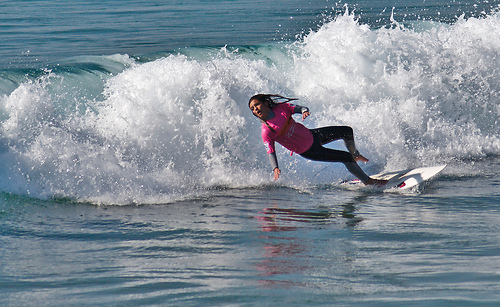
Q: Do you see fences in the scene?
A: No, there are no fences.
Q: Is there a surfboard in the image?
A: Yes, there is a surfboard.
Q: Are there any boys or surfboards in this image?
A: Yes, there is a surfboard.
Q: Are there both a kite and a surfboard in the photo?
A: No, there is a surfboard but no kites.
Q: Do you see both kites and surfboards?
A: No, there is a surfboard but no kites.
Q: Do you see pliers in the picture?
A: No, there are no pliers.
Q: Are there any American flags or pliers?
A: No, there are no pliers or American flags.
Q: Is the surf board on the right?
A: Yes, the surf board is on the right of the image.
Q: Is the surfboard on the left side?
A: No, the surfboard is on the right of the image.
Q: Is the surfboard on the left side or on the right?
A: The surfboard is on the right of the image.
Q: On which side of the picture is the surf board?
A: The surf board is on the right of the image.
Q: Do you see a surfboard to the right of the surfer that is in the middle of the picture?
A: Yes, there is a surfboard to the right of the surfer.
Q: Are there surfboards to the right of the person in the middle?
A: Yes, there is a surfboard to the right of the surfer.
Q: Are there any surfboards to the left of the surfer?
A: No, the surfboard is to the right of the surfer.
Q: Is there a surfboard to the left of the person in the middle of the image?
A: No, the surfboard is to the right of the surfer.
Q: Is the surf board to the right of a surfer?
A: Yes, the surf board is to the right of a surfer.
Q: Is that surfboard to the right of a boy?
A: No, the surfboard is to the right of a surfer.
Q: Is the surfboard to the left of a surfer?
A: No, the surfboard is to the right of a surfer.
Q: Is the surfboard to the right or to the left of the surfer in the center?
A: The surfboard is to the right of the surfer.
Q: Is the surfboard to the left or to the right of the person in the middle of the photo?
A: The surfboard is to the right of the surfer.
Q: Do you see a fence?
A: No, there are no fences.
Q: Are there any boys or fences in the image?
A: No, there are no fences or boys.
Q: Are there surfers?
A: Yes, there is a surfer.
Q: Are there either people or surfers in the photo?
A: Yes, there is a surfer.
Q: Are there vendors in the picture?
A: No, there are no vendors.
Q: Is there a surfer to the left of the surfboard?
A: Yes, there is a surfer to the left of the surfboard.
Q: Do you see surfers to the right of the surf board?
A: No, the surfer is to the left of the surf board.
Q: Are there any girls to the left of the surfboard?
A: No, there is a surfer to the left of the surfboard.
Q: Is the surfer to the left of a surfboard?
A: Yes, the surfer is to the left of a surfboard.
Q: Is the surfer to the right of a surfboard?
A: No, the surfer is to the left of a surfboard.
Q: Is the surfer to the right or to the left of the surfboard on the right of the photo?
A: The surfer is to the left of the surfboard.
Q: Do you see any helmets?
A: No, there are no helmets.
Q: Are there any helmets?
A: No, there are no helmets.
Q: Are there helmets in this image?
A: No, there are no helmets.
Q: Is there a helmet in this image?
A: No, there are no helmets.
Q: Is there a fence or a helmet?
A: No, there are no helmets or fences.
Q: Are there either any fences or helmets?
A: No, there are no helmets or fences.